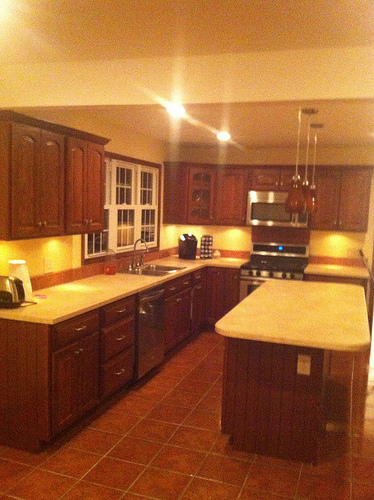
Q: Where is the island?
A: In kitchen.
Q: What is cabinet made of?
A: Wood.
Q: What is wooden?
A: Cabinet.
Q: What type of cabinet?
A: Hanging.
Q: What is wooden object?
A: Cabinet.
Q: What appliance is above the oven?
A: Microwave.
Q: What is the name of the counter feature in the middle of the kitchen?
A: Island.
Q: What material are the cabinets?
A: Wooden.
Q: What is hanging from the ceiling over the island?
A: Lighting.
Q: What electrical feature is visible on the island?
A: Outlet.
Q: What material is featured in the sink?
A: Stainless steel.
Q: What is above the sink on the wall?
A: Windows.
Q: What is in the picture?
A: A kitchen.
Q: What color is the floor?
A: Brown.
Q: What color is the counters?
A: White.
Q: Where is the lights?
A: On the ceiling.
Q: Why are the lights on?
A: Someone turned them on.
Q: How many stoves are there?
A: One.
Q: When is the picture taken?
A: Night.